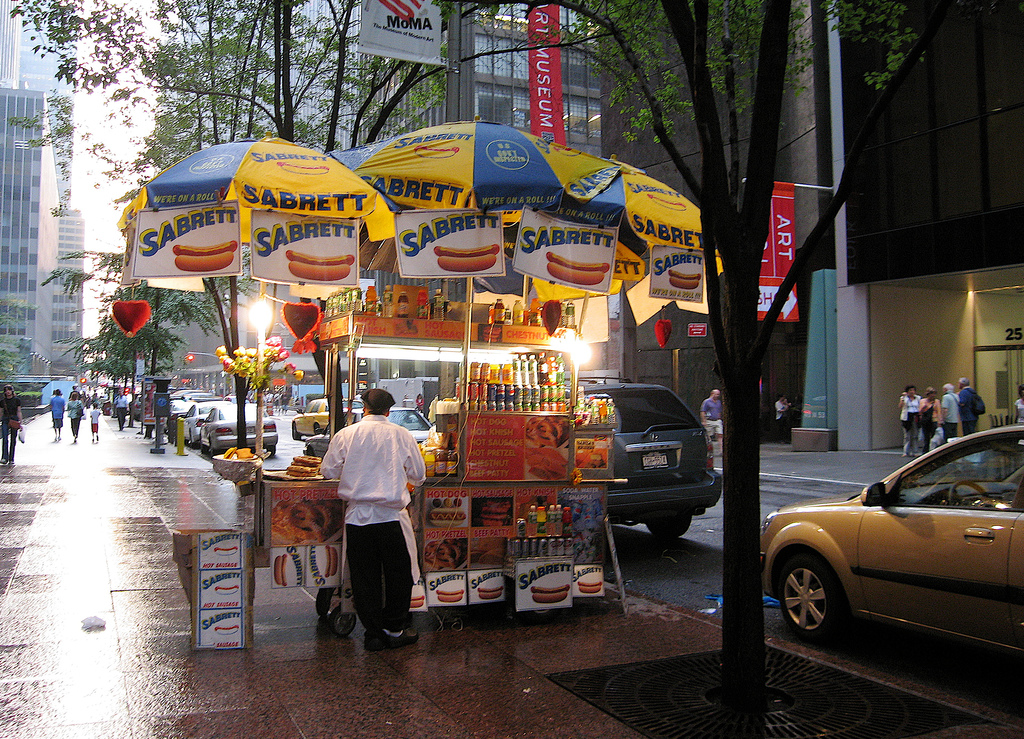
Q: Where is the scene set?
A: Next to a Sabrett Stand.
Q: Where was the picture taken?
A: Outside of a Museum.